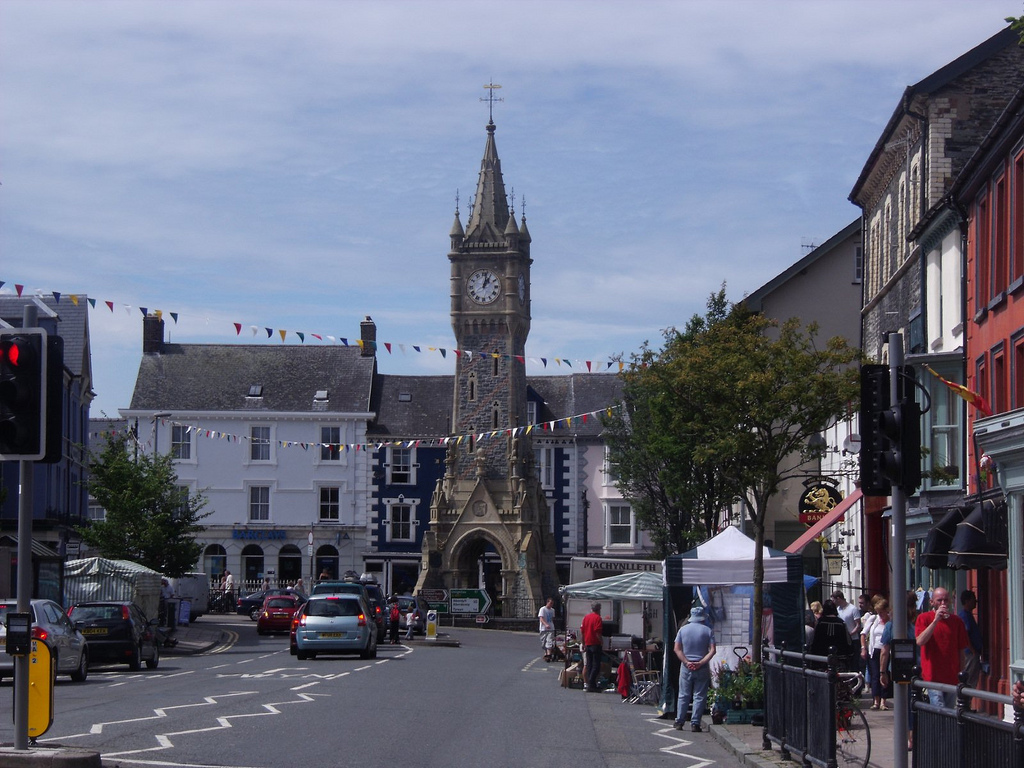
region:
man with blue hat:
[663, 599, 721, 730]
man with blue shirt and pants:
[662, 599, 721, 733]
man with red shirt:
[561, 596, 612, 695]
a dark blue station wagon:
[54, 590, 159, 674]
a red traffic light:
[1, 321, 97, 759]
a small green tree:
[586, 273, 865, 720]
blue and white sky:
[0, 1, 1016, 412]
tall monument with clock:
[386, 71, 565, 625]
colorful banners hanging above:
[0, 269, 683, 476]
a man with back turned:
[670, 598, 719, 739]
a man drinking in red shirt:
[907, 585, 981, 677]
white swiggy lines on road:
[89, 670, 317, 759]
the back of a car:
[291, 585, 396, 661]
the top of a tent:
[659, 512, 795, 592]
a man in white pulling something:
[528, 595, 558, 662]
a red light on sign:
[2, 326, 25, 391]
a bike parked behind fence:
[836, 672, 875, 767]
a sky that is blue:
[254, 110, 441, 253]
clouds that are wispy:
[152, 69, 348, 180]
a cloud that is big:
[40, 86, 215, 243]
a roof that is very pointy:
[453, 98, 534, 232]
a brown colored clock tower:
[403, 133, 560, 615]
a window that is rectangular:
[222, 414, 277, 478]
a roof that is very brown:
[93, 306, 394, 440]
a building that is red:
[936, 168, 1020, 440]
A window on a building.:
[321, 478, 348, 523]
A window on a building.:
[252, 472, 285, 515]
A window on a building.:
[319, 421, 345, 463]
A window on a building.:
[166, 418, 199, 463]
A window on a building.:
[385, 444, 412, 476]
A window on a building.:
[384, 498, 427, 550]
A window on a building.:
[604, 500, 639, 542]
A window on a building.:
[606, 443, 633, 485]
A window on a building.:
[989, 351, 1012, 406]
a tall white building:
[125, 308, 373, 599]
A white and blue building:
[371, 374, 575, 606]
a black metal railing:
[756, 636, 837, 767]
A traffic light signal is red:
[2, 339, 23, 369]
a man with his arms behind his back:
[667, 606, 716, 731]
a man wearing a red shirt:
[579, 598, 606, 691]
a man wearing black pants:
[577, 600, 604, 693]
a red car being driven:
[257, 589, 299, 635]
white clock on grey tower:
[447, 83, 531, 321]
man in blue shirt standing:
[665, 602, 719, 735]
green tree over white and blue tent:
[615, 283, 879, 729]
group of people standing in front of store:
[813, 565, 975, 724]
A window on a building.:
[318, 427, 344, 472]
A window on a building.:
[315, 473, 347, 515]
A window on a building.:
[247, 485, 266, 514]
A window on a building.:
[250, 416, 274, 461]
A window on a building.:
[161, 424, 185, 460]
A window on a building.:
[204, 552, 231, 576]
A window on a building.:
[242, 544, 258, 577]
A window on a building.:
[283, 541, 304, 586]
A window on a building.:
[321, 541, 337, 577]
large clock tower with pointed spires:
[401, 90, 548, 622]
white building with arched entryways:
[122, 301, 383, 599]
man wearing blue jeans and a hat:
[666, 602, 720, 730]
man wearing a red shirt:
[576, 600, 614, 698]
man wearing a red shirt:
[915, 588, 976, 705]